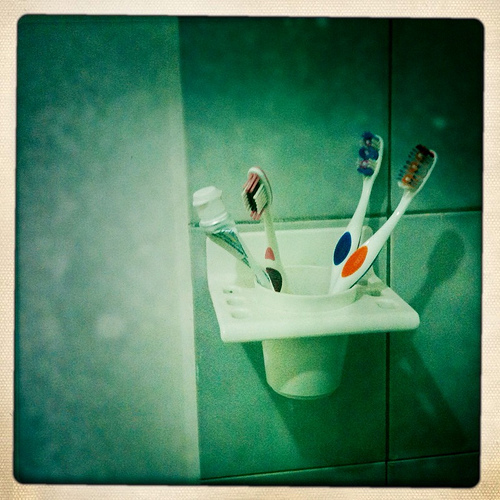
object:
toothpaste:
[191, 187, 273, 292]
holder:
[256, 265, 356, 400]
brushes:
[241, 132, 438, 295]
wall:
[16, 12, 485, 496]